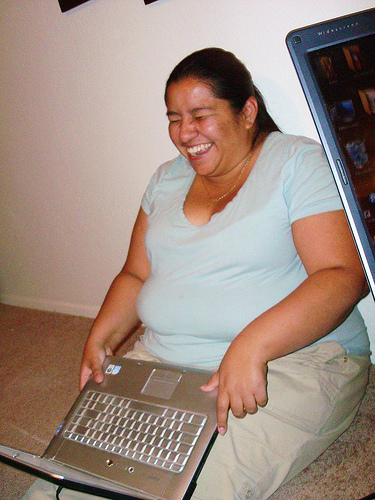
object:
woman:
[79, 47, 367, 496]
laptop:
[0, 354, 216, 497]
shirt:
[140, 131, 371, 369]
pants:
[20, 337, 367, 500]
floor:
[0, 449, 134, 495]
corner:
[304, 34, 375, 134]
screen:
[306, 34, 375, 251]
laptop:
[283, 4, 374, 295]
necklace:
[201, 152, 252, 201]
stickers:
[104, 364, 121, 375]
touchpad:
[141, 368, 182, 399]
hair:
[164, 47, 280, 149]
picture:
[0, 0, 375, 499]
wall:
[0, 0, 375, 352]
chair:
[0, 302, 375, 500]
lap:
[124, 341, 329, 500]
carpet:
[0, 299, 375, 499]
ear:
[242, 96, 257, 129]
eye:
[170, 118, 181, 122]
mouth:
[181, 142, 214, 161]